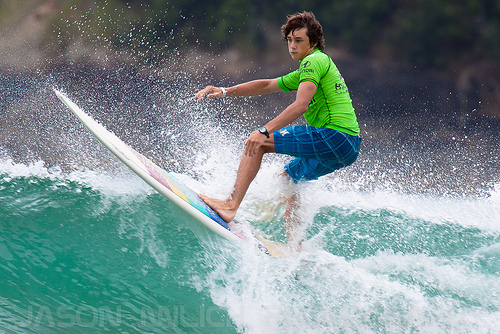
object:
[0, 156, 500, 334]
wave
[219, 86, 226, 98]
band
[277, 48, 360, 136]
green shirt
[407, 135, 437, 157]
ground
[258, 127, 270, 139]
watch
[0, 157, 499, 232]
waveedge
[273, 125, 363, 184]
shorts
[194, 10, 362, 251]
male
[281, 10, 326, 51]
hair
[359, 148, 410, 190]
floor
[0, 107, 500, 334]
splash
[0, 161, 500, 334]
lake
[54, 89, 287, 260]
board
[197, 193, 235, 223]
foot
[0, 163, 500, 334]
water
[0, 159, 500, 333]
ocean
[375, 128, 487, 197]
spray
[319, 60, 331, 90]
stitching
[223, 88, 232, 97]
wrist